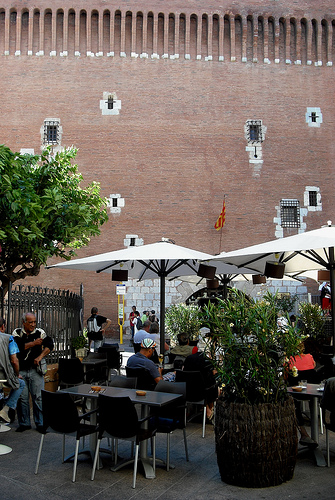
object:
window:
[47, 119, 59, 148]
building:
[2, 1, 332, 351]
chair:
[90, 393, 158, 488]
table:
[58, 380, 194, 478]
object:
[280, 351, 318, 374]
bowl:
[133, 386, 146, 395]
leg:
[132, 440, 141, 489]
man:
[10, 309, 51, 434]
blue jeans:
[11, 369, 49, 431]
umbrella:
[43, 234, 253, 371]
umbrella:
[199, 221, 334, 274]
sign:
[115, 285, 126, 295]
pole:
[116, 292, 126, 347]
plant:
[168, 280, 323, 403]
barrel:
[214, 384, 299, 489]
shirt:
[10, 327, 54, 374]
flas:
[208, 197, 234, 236]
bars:
[49, 128, 57, 138]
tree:
[0, 139, 110, 334]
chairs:
[34, 389, 99, 485]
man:
[127, 326, 163, 389]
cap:
[130, 330, 159, 345]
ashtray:
[87, 384, 103, 397]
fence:
[1, 276, 84, 363]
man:
[0, 317, 24, 427]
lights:
[111, 266, 129, 284]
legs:
[90, 439, 99, 482]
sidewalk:
[0, 407, 335, 499]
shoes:
[13, 422, 29, 433]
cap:
[139, 338, 158, 351]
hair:
[22, 310, 35, 325]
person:
[83, 306, 111, 353]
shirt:
[82, 314, 108, 341]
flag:
[214, 198, 226, 233]